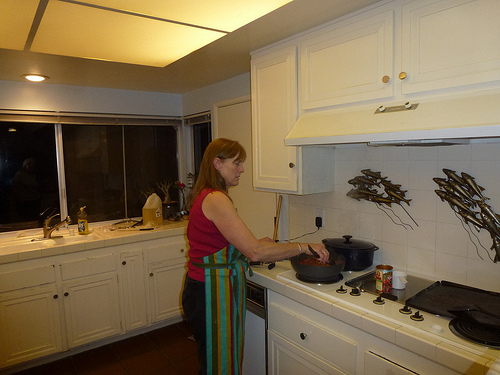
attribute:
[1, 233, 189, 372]
cabinet — white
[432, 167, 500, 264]
fish sculpture — decorative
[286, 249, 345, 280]
skillet — cast iron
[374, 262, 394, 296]
can — tomato sauce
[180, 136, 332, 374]
woman — cooking, turning something, stirring, standing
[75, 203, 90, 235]
bottle — dish soap, yellow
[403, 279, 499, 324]
cookie sheet — metal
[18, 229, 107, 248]
kitchen sink — white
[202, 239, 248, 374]
apron — colorful, striped, long, multi-colored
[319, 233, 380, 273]
pot — black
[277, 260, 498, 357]
stove top — white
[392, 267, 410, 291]
cup — white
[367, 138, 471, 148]
vent — white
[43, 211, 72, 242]
faucet — chrome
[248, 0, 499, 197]
cabinet — white